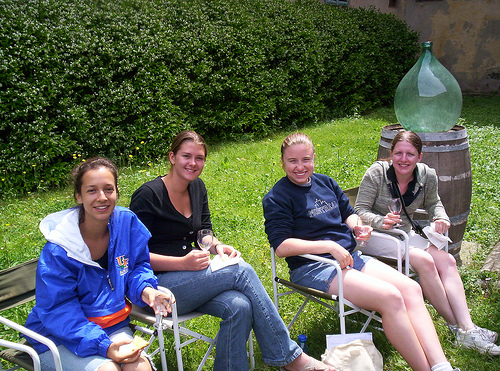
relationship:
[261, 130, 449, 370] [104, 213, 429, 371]
lady holding glasses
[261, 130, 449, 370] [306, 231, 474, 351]
lady wearing shorts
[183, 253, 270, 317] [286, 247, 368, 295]
one woman wearing jeans and two women shorts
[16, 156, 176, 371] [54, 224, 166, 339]
person seated wearing a blue jacket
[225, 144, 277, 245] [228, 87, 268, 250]
weeds with flowers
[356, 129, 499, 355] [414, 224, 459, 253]
person holding a glass and a napkin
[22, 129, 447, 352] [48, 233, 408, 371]
four female friends relaxing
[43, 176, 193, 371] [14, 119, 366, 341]
person sitting on chair in yard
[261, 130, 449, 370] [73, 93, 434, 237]
lady sitting on chair in yard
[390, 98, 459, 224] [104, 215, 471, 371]
person sitting on chair in yard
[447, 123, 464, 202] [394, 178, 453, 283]
barrel behind woman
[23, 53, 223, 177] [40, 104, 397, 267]
thick hedges growing around yard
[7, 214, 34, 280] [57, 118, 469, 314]
grass growing in yard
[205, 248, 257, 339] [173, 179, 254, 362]
jeans on woman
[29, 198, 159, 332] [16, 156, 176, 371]
jacket on person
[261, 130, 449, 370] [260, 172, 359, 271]
lady wearing sweater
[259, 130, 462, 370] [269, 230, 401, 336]
lady sitting in chair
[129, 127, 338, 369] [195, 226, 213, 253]
lady holding glass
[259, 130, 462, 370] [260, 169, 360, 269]
lady wearing shirt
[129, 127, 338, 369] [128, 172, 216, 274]
lady wearing shirt